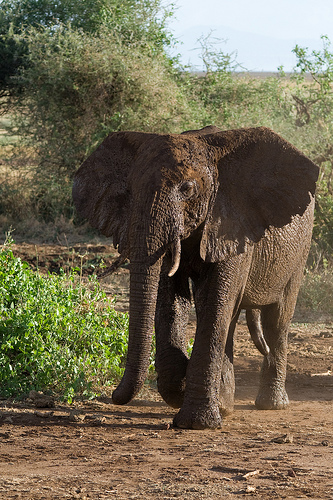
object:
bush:
[0, 242, 155, 392]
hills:
[155, 69, 320, 86]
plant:
[0, 230, 130, 400]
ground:
[3, 431, 332, 496]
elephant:
[69, 124, 319, 429]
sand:
[0, 405, 260, 498]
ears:
[200, 124, 321, 262]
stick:
[214, 462, 260, 482]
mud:
[85, 382, 329, 494]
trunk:
[110, 186, 167, 407]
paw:
[171, 407, 220, 429]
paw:
[156, 378, 183, 410]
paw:
[216, 400, 232, 412]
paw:
[254, 390, 288, 408]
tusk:
[166, 235, 182, 279]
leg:
[182, 264, 248, 397]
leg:
[155, 268, 192, 408]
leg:
[254, 275, 306, 388]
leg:
[218, 303, 236, 388]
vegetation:
[0, 240, 194, 401]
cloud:
[161, 3, 333, 76]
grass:
[0, 107, 126, 254]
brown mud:
[0, 322, 333, 499]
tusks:
[95, 243, 131, 281]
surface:
[6, 426, 329, 498]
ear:
[71, 132, 137, 258]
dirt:
[0, 314, 333, 500]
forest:
[0, 1, 331, 304]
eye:
[178, 176, 196, 198]